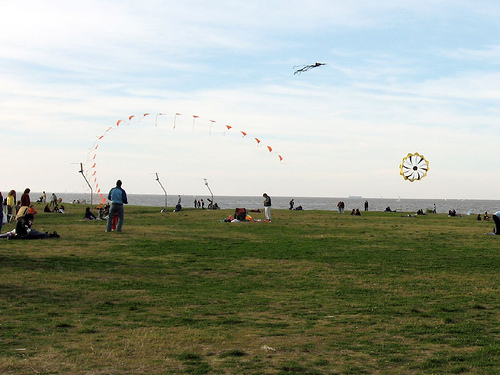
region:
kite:
[385, 148, 427, 186]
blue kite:
[283, 50, 326, 104]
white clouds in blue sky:
[7, 23, 69, 105]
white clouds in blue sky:
[8, 85, 35, 154]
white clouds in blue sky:
[91, 32, 153, 84]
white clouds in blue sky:
[173, 29, 221, 123]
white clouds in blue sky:
[174, 140, 210, 163]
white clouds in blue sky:
[216, 23, 259, 106]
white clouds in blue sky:
[368, 34, 427, 108]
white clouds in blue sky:
[453, 121, 493, 200]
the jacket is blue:
[101, 187, 142, 207]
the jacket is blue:
[98, 192, 146, 215]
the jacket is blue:
[108, 184, 135, 216]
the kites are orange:
[80, 121, 117, 228]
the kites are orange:
[121, 105, 196, 129]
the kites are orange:
[238, 111, 299, 167]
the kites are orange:
[84, 89, 112, 157]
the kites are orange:
[113, 101, 232, 153]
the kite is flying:
[272, 30, 374, 116]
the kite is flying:
[388, 142, 469, 229]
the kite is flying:
[271, 45, 329, 96]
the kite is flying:
[252, 40, 496, 197]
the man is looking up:
[95, 168, 135, 234]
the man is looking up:
[91, 165, 151, 265]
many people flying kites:
[5, 185, 498, 233]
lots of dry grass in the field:
[6, 252, 493, 372]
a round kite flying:
[397, 152, 429, 182]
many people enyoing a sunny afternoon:
[1, 177, 488, 234]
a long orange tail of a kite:
[101, 112, 293, 161]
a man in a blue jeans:
[106, 203, 126, 233]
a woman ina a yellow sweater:
[6, 194, 15, 208]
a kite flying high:
[293, 62, 327, 75]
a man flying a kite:
[107, 181, 124, 238]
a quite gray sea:
[239, 192, 492, 209]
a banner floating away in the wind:
[81, 101, 286, 191]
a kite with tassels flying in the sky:
[291, 47, 334, 82]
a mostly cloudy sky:
[50, 10, 262, 97]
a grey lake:
[302, 192, 483, 209]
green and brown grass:
[73, 250, 423, 347]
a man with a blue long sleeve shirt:
[104, 177, 133, 232]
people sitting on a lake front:
[7, 178, 73, 240]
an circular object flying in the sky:
[392, 140, 439, 190]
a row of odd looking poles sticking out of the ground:
[62, 153, 229, 212]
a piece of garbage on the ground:
[252, 330, 287, 359]